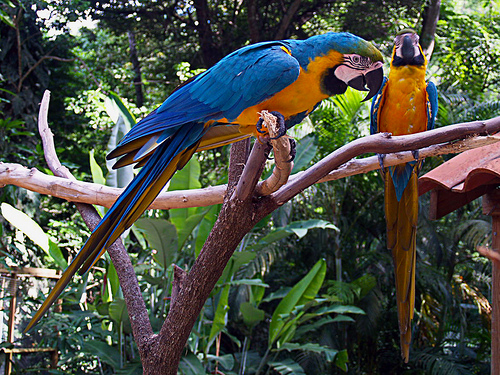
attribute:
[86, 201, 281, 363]
tree — edge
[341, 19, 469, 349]
parrot — perched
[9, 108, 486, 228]
perch — wooden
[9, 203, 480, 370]
trees — dark, green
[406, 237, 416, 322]
feather — yellow, long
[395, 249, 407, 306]
feather — yellow, long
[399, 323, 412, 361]
feather — yellow, long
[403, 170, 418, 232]
feather — yellow, long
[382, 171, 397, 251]
feather — yellow, long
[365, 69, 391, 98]
beak — black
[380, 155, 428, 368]
tail — long, yellow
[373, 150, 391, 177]
twig — part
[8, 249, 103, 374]
structure — wood, unknown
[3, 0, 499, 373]
plants — green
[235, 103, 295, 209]
branch — wooden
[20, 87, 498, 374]
tree — part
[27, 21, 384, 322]
bird — blue, yellow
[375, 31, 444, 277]
bird — blue, yellow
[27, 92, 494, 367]
bird perch — wooden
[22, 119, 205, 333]
tail — yellow, blue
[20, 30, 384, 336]
macaw — giant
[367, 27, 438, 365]
macaw — giant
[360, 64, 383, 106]
beak — black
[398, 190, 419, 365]
feathers — yellow, tail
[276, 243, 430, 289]
foliage — green, lush